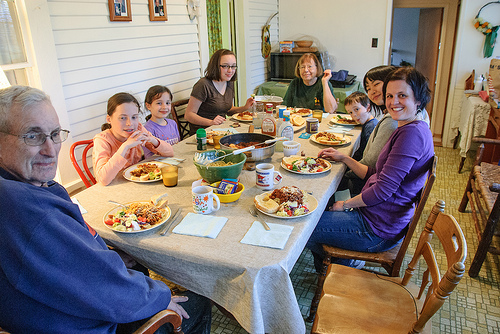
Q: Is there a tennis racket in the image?
A: No, there are no rackets.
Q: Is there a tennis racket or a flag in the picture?
A: No, there are no rackets or flags.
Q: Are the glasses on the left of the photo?
A: Yes, the glasses are on the left of the image.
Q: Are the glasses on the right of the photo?
A: No, the glasses are on the left of the image.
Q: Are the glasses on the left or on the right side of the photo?
A: The glasses are on the left of the image.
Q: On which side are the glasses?
A: The glasses are on the left of the image.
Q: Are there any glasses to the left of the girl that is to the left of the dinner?
A: Yes, there are glasses to the left of the girl.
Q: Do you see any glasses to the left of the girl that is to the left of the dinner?
A: Yes, there are glasses to the left of the girl.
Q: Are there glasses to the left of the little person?
A: Yes, there are glasses to the left of the girl.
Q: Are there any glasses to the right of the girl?
A: No, the glasses are to the left of the girl.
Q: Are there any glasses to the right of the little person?
A: No, the glasses are to the left of the girl.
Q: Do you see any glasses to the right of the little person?
A: No, the glasses are to the left of the girl.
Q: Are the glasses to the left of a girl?
A: Yes, the glasses are to the left of a girl.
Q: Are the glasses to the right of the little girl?
A: No, the glasses are to the left of the girl.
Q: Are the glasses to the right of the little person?
A: No, the glasses are to the left of the girl.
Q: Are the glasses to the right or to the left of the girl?
A: The glasses are to the left of the girl.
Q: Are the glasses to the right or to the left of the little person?
A: The glasses are to the left of the girl.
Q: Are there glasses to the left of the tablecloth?
A: Yes, there are glasses to the left of the tablecloth.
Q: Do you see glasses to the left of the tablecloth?
A: Yes, there are glasses to the left of the tablecloth.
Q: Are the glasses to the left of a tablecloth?
A: Yes, the glasses are to the left of a tablecloth.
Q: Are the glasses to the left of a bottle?
A: No, the glasses are to the left of a tablecloth.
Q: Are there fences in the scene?
A: No, there are no fences.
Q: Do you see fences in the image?
A: No, there are no fences.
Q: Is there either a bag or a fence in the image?
A: No, there are no fences or bags.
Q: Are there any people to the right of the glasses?
A: Yes, there is a person to the right of the glasses.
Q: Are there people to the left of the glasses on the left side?
A: No, the person is to the right of the glasses.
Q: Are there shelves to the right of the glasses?
A: No, there is a person to the right of the glasses.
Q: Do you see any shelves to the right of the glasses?
A: No, there is a person to the right of the glasses.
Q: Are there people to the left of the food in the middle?
A: Yes, there is a person to the left of the food.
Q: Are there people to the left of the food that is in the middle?
A: Yes, there is a person to the left of the food.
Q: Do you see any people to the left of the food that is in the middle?
A: Yes, there is a person to the left of the food.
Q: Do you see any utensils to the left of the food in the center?
A: No, there is a person to the left of the food.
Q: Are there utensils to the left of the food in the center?
A: No, there is a person to the left of the food.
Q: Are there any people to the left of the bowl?
A: Yes, there is a person to the left of the bowl.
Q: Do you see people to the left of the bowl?
A: Yes, there is a person to the left of the bowl.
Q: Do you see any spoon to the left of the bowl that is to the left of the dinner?
A: No, there is a person to the left of the bowl.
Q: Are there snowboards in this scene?
A: No, there are no snowboards.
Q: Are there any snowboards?
A: No, there are no snowboards.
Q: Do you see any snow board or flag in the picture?
A: No, there are no snowboards or flags.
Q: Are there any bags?
A: No, there are no bags.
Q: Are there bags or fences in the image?
A: No, there are no bags or fences.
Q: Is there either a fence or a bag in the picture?
A: No, there are no bags or fences.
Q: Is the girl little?
A: Yes, the girl is little.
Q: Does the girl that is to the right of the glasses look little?
A: Yes, the girl is little.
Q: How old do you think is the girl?
A: The girl is little.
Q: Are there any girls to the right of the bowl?
A: No, the girl is to the left of the bowl.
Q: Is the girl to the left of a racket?
A: No, the girl is to the left of the bowl.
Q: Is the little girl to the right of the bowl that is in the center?
A: No, the girl is to the left of the bowl.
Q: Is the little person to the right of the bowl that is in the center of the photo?
A: No, the girl is to the left of the bowl.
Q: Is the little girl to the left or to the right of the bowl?
A: The girl is to the left of the bowl.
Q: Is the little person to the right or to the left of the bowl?
A: The girl is to the left of the bowl.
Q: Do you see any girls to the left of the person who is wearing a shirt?
A: Yes, there is a girl to the left of the person.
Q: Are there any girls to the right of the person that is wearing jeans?
A: No, the girl is to the left of the person.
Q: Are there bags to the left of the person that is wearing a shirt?
A: No, there is a girl to the left of the person.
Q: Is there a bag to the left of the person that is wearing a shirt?
A: No, there is a girl to the left of the person.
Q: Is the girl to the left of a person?
A: Yes, the girl is to the left of a person.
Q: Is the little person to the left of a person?
A: Yes, the girl is to the left of a person.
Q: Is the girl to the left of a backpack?
A: No, the girl is to the left of a person.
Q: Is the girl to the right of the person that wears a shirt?
A: No, the girl is to the left of the person.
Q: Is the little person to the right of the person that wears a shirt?
A: No, the girl is to the left of the person.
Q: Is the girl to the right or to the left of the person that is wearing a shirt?
A: The girl is to the left of the person.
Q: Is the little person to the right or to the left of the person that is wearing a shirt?
A: The girl is to the left of the person.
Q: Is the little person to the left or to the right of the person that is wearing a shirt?
A: The girl is to the left of the person.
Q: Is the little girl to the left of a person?
A: Yes, the girl is to the left of a person.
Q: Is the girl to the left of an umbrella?
A: No, the girl is to the left of a person.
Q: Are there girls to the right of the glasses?
A: Yes, there is a girl to the right of the glasses.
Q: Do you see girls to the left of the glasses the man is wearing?
A: No, the girl is to the right of the glasses.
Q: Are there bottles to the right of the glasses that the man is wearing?
A: No, there is a girl to the right of the glasses.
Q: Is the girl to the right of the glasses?
A: Yes, the girl is to the right of the glasses.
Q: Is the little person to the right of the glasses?
A: Yes, the girl is to the right of the glasses.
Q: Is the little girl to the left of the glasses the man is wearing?
A: No, the girl is to the right of the glasses.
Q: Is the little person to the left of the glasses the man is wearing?
A: No, the girl is to the right of the glasses.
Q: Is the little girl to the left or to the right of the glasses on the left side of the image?
A: The girl is to the right of the glasses.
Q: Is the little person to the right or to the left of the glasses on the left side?
A: The girl is to the right of the glasses.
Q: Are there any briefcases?
A: No, there are no briefcases.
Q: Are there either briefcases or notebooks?
A: No, there are no briefcases or notebooks.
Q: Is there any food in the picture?
A: Yes, there is food.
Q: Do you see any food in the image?
A: Yes, there is food.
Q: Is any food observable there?
A: Yes, there is food.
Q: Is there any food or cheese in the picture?
A: Yes, there is food.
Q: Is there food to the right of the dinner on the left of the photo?
A: Yes, there is food to the right of the dinner.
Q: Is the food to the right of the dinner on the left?
A: Yes, the food is to the right of the dinner.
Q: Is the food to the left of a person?
A: No, the food is to the right of a person.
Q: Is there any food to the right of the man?
A: Yes, there is food to the right of the man.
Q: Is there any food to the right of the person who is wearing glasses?
A: Yes, there is food to the right of the man.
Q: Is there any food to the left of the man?
A: No, the food is to the right of the man.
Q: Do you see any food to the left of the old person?
A: No, the food is to the right of the man.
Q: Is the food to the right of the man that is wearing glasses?
A: Yes, the food is to the right of the man.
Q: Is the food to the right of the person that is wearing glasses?
A: Yes, the food is to the right of the man.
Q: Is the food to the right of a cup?
A: No, the food is to the right of the man.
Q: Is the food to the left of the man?
A: No, the food is to the right of the man.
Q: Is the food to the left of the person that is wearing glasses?
A: No, the food is to the right of the man.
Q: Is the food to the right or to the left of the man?
A: The food is to the right of the man.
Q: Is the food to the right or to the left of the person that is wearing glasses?
A: The food is to the right of the man.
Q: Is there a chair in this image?
A: Yes, there is a chair.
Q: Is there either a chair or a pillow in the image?
A: Yes, there is a chair.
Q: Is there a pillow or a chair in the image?
A: Yes, there is a chair.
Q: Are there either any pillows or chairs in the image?
A: Yes, there is a chair.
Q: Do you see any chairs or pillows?
A: Yes, there is a chair.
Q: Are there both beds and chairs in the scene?
A: No, there is a chair but no beds.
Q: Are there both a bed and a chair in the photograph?
A: No, there is a chair but no beds.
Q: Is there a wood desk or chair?
A: Yes, there is a wood chair.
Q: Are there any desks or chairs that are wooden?
A: Yes, the chair is wooden.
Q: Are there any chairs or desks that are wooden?
A: Yes, the chair is wooden.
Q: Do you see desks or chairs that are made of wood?
A: Yes, the chair is made of wood.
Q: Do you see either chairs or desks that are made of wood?
A: Yes, the chair is made of wood.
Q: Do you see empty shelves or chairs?
A: Yes, there is an empty chair.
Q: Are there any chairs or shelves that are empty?
A: Yes, the chair is empty.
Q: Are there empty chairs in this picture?
A: Yes, there is an empty chair.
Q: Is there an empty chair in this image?
A: Yes, there is an empty chair.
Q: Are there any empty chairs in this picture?
A: Yes, there is an empty chair.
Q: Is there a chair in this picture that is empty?
A: Yes, there is a chair that is empty.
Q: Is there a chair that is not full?
A: Yes, there is a empty chair.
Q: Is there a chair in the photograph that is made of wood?
A: Yes, there is a chair that is made of wood.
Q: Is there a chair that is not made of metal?
A: Yes, there is a chair that is made of wood.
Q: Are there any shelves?
A: No, there are no shelves.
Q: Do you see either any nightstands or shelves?
A: No, there are no shelves or nightstands.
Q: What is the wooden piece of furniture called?
A: The piece of furniture is a chair.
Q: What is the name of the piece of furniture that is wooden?
A: The piece of furniture is a chair.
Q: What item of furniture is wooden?
A: The piece of furniture is a chair.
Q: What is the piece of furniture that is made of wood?
A: The piece of furniture is a chair.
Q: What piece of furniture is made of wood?
A: The piece of furniture is a chair.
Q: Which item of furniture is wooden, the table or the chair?
A: The chair is wooden.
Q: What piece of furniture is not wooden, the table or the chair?
A: The table is not wooden.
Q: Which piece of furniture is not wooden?
A: The piece of furniture is a table.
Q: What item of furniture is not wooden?
A: The piece of furniture is a table.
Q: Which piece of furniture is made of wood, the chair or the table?
A: The chair is made of wood.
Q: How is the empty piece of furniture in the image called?
A: The piece of furniture is a chair.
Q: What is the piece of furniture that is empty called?
A: The piece of furniture is a chair.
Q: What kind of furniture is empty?
A: The furniture is a chair.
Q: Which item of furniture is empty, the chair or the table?
A: The chair is empty.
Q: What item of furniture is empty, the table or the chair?
A: The chair is empty.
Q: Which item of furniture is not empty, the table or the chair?
A: The table is not empty.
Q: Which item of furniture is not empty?
A: The piece of furniture is a table.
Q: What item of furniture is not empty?
A: The piece of furniture is a table.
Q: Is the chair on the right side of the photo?
A: Yes, the chair is on the right of the image.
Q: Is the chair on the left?
A: No, the chair is on the right of the image.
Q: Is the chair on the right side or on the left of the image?
A: The chair is on the right of the image.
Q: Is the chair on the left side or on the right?
A: The chair is on the right of the image.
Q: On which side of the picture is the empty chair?
A: The chair is on the right of the image.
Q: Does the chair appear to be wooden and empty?
A: Yes, the chair is wooden and empty.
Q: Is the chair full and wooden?
A: No, the chair is wooden but empty.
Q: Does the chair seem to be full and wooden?
A: No, the chair is wooden but empty.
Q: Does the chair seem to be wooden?
A: Yes, the chair is wooden.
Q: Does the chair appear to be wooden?
A: Yes, the chair is wooden.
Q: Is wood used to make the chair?
A: Yes, the chair is made of wood.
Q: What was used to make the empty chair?
A: The chair is made of wood.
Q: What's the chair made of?
A: The chair is made of wood.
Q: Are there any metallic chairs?
A: No, there is a chair but it is wooden.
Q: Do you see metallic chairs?
A: No, there is a chair but it is wooden.